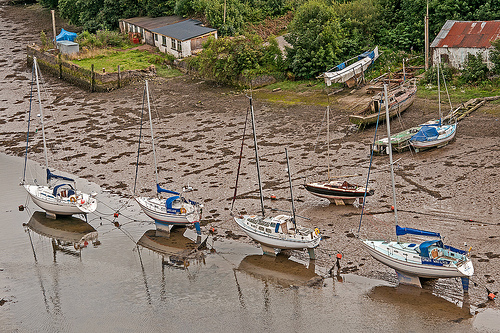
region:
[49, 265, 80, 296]
a body of water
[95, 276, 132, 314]
a body of water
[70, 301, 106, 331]
a body of water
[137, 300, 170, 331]
a body of water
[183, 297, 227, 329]
a body of water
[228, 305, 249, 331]
a body of water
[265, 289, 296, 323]
a body of water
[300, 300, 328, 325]
a body of water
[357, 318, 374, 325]
a body of water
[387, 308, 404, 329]
a body of water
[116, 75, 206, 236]
Boat near the shore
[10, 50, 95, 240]
Boat near the shore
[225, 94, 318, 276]
Boat near the shore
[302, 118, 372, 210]
Boat in the sand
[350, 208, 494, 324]
Boat near the shore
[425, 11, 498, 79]
House in the background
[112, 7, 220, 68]
House in the background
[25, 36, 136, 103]
Fence around the grass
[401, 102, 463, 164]
Boat in the sand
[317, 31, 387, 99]
Boat in the grass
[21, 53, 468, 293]
four boats in a row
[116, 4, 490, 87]
houses on the shore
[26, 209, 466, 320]
boats reflected in the water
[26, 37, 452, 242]
masts of the boats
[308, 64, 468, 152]
boats in the mud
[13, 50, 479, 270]
tracks in the mud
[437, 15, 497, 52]
rusted roof of building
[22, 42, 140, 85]
fence around grass yard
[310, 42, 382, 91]
boat in the grass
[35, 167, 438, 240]
rolled up sails on the boats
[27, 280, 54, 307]
a body of water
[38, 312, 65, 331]
a body of water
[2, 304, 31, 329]
a body of water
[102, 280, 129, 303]
a body of water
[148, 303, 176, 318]
a body of water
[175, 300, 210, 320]
a body of water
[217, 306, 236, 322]
a body of water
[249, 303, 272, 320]
a body of water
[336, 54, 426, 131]
wooden boat on a beach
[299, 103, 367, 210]
boat in the sand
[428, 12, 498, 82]
building with a rusted roof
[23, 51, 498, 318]
boats moored on the beach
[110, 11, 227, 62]
buildings with flat roofs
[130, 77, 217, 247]
sailboat on the beach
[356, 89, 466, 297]
sailboat on the beach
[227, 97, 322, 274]
white boat on the beach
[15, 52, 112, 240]
white sailboat on the beach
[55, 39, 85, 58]
small white garden shed